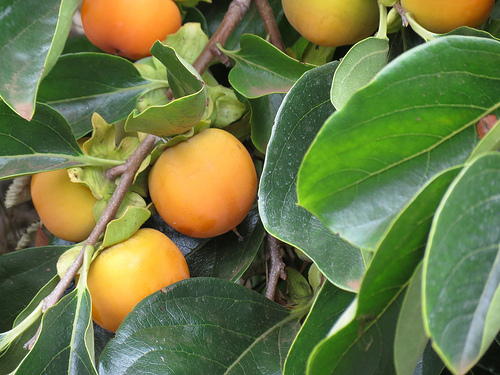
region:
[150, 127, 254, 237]
a yellow fruit on tree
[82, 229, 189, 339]
a yellow fruit on tree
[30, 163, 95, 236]
a yellow fruit on tree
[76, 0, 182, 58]
a yellow fruit on tree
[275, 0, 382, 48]
a yellow fruit on tree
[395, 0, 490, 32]
a yellow fruit on tree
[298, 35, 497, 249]
a large green leaf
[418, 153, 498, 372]
a large green leaf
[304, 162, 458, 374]
a large green leaf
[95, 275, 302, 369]
a large green leaf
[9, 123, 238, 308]
Fruit is orange color.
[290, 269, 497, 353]
Leaves are green color.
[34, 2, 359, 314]
Fruits are hanging from the stem.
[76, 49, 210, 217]
Branch is brown color.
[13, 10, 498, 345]
Day time picture.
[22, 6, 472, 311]
Six fruits are in branches.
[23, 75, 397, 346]
Sunlight reflection is seen in leaves.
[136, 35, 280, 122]
Leaves are attached to the branches.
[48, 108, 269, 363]
Fruits are round shape.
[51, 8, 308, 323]
Fruits are ripen.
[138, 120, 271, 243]
An orange colored fruit.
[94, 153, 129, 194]
Stem holding fruit to branch.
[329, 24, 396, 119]
Backside of a leaf.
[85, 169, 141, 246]
A brown branch of the tree.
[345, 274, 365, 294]
A pink spot on the leaf.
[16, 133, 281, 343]
A cluster of fruit on the tree.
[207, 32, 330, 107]
A leaf attached to the branch of the tree.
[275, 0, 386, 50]
A piece of fruit that is not completely ripe.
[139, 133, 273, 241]
A fully ripe piece of fruit.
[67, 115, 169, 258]
Light green leaves around fruit.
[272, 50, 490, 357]
these are some leaves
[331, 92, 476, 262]
the leaves are big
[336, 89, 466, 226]
the leaves are green in color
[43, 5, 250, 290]
these are some fruits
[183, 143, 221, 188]
the fruit is orange in color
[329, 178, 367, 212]
the leaf is shiny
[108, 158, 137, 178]
this is a stalk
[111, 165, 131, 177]
the stalk is brown in color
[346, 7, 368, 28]
the fruit part is green in color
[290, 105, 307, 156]
there are several stomata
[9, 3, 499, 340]
This is a fruit tree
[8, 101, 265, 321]
Fruits are orange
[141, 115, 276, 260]
This is a pear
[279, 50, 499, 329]
The leaves are dark green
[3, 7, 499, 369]
A tree in the photo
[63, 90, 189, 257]
light green leaves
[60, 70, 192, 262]
The light green leaves are the fruit's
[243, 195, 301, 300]
Branches are light brown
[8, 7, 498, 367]
This is a close up of the tree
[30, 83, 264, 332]
Fruits are underneath the leaves